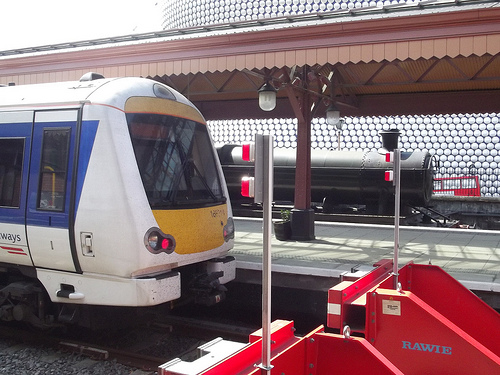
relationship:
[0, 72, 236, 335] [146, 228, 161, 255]
train has light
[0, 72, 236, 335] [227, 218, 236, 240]
train has light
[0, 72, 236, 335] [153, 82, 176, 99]
train has light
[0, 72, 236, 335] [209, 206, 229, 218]
train has number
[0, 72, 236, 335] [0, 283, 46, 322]
train has part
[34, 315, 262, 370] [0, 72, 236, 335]
tracks for train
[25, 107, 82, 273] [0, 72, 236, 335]
door of train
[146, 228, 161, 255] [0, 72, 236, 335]
light on train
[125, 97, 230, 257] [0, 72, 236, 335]
portion of train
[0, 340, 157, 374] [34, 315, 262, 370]
gravel next to tracks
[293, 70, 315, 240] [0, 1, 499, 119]
beam holding up roof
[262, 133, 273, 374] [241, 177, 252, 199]
pole has light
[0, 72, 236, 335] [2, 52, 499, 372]
train at station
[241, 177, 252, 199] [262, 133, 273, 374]
light on pole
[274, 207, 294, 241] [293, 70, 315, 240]
plant by pole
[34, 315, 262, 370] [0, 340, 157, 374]
tracks on gravel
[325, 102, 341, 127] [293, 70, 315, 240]
light on beam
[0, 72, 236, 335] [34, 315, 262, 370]
train on track